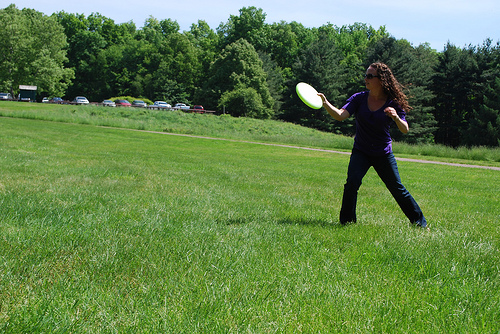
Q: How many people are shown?
A: One.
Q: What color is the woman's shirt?
A: Purple.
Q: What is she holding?
A: A frisbee.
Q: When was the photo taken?
A: Daytime.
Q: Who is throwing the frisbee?
A: The woman.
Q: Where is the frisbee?
A: In the woman's hand.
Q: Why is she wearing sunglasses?
A: It is sunny.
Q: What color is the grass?
A: Green.